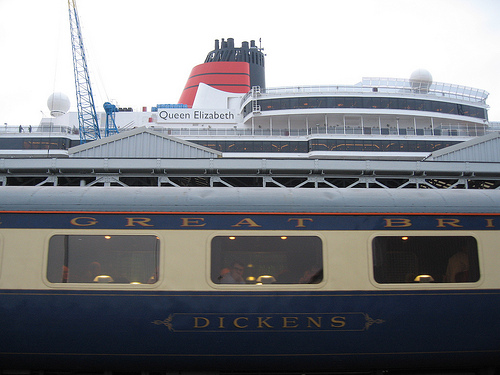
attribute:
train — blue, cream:
[7, 189, 494, 373]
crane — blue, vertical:
[65, 2, 117, 147]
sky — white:
[88, 0, 195, 115]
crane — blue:
[56, 0, 113, 145]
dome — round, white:
[41, 87, 70, 114]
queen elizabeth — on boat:
[156, 107, 238, 121]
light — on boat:
[101, 230, 114, 244]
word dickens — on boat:
[193, 311, 350, 331]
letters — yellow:
[65, 208, 315, 229]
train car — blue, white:
[4, 184, 496, 360]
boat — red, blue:
[0, 31, 500, 185]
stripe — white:
[4, 156, 499, 170]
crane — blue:
[63, 0, 100, 144]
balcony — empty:
[249, 91, 491, 144]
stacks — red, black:
[206, 34, 264, 66]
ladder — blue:
[60, 3, 100, 140]